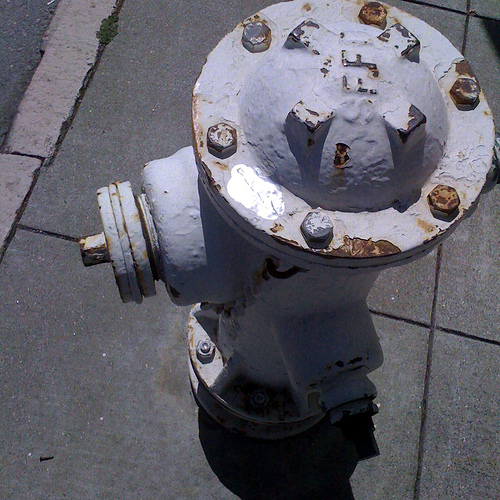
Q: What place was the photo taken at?
A: It was taken at the sidewalk.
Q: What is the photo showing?
A: It is showing a sidewalk.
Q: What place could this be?
A: It is a sidewalk.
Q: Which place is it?
A: It is a sidewalk.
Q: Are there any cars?
A: No, there are no cars.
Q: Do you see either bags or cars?
A: No, there are no cars or bags.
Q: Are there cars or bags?
A: No, there are no cars or bags.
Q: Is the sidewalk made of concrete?
A: Yes, the sidewalk is made of concrete.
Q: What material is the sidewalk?
A: The sidewalk is made of concrete.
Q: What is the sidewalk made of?
A: The sidewalk is made of concrete.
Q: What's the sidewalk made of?
A: The sidewalk is made of concrete.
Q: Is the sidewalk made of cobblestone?
A: No, the sidewalk is made of concrete.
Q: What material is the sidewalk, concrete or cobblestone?
A: The sidewalk is made of concrete.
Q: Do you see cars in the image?
A: No, there are no cars.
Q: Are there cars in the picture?
A: No, there are no cars.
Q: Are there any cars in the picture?
A: No, there are no cars.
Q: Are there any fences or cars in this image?
A: No, there are no cars or fences.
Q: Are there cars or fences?
A: No, there are no cars or fences.